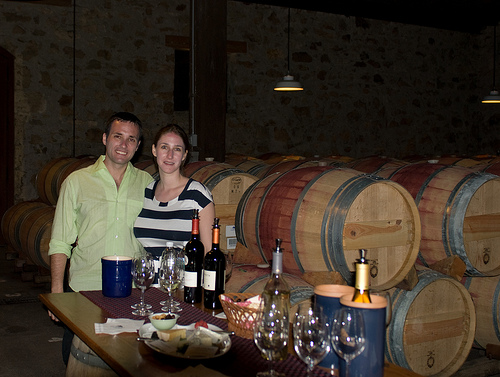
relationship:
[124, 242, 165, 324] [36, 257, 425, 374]
glass on table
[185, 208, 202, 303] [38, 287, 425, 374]
bottle on table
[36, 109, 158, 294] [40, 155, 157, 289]
man in shirt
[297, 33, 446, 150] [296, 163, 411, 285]
stone wall behind keg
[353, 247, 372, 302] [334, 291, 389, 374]
bottle in blue pot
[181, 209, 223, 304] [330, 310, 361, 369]
wine in glasses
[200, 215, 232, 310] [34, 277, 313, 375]
wine on table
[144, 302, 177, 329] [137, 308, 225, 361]
bowl with plate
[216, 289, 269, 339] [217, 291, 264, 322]
basket with napkin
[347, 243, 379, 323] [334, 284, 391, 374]
bottle in chiller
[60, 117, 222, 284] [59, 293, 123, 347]
people on table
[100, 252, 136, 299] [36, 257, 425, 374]
cup on table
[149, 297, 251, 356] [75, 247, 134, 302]
flowers in vase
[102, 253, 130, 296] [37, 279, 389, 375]
vase on table